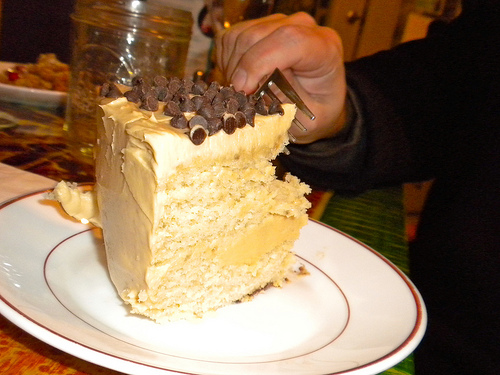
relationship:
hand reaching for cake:
[211, 13, 353, 145] [91, 86, 315, 316]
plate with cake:
[1, 177, 422, 372] [91, 86, 315, 316]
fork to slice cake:
[236, 66, 317, 156] [91, 86, 315, 316]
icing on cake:
[76, 89, 194, 305] [82, 138, 265, 275]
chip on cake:
[190, 127, 208, 147] [98, 107, 313, 296]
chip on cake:
[170, 114, 215, 137] [97, 143, 294, 281]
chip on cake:
[198, 110, 238, 140] [109, 95, 306, 295]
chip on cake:
[202, 89, 238, 133] [79, 96, 252, 275]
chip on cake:
[216, 113, 237, 130] [118, 136, 324, 317]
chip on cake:
[186, 93, 237, 128] [138, 152, 267, 288]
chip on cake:
[145, 96, 205, 139] [115, 106, 284, 320]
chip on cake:
[158, 87, 217, 122] [127, 133, 284, 306]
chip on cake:
[147, 83, 235, 130] [83, 95, 278, 275]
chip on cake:
[162, 78, 227, 138] [120, 164, 250, 287]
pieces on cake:
[108, 67, 183, 123] [92, 140, 276, 282]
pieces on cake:
[108, 67, 183, 123] [108, 154, 280, 292]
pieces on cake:
[108, 67, 183, 123] [119, 123, 300, 299]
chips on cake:
[149, 89, 209, 148] [135, 151, 272, 319]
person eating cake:
[282, 8, 429, 133] [149, 119, 266, 302]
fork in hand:
[236, 66, 317, 138] [219, 15, 279, 76]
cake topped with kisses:
[104, 89, 290, 336] [145, 83, 224, 150]